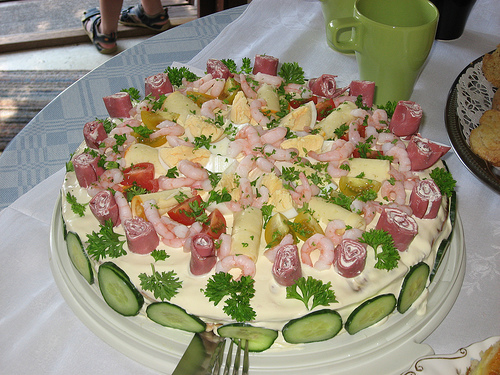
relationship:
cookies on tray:
[185, 109, 360, 244] [373, 320, 425, 347]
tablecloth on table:
[22, 5, 494, 373] [2, 1, 497, 372]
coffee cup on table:
[328, 2, 439, 110] [2, 1, 497, 372]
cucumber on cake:
[277, 307, 346, 346] [50, 53, 470, 361]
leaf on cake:
[199, 270, 257, 323] [111, 73, 482, 321]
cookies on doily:
[480, 40, 499, 86] [453, 52, 498, 174]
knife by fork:
[176, 327, 208, 373] [215, 325, 248, 373]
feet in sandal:
[82, 5, 160, 49] [79, 6, 119, 56]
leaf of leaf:
[199, 270, 257, 323] [199, 270, 257, 323]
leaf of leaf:
[204, 268, 234, 307] [199, 270, 257, 323]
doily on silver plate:
[452, 53, 483, 129] [420, 33, 497, 191]